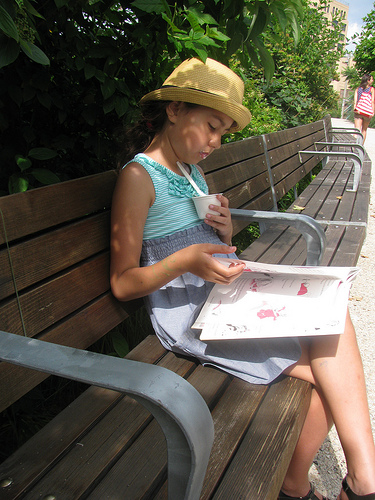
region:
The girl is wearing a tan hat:
[141, 48, 259, 132]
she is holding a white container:
[191, 189, 231, 219]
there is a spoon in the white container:
[174, 160, 206, 201]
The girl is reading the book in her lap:
[195, 258, 356, 344]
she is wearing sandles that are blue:
[339, 478, 373, 499]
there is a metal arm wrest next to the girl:
[217, 204, 333, 265]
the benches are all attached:
[255, 113, 373, 231]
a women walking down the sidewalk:
[355, 75, 373, 151]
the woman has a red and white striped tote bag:
[351, 88, 374, 116]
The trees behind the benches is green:
[222, 18, 333, 134]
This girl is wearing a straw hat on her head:
[182, 47, 271, 130]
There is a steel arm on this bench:
[124, 352, 147, 469]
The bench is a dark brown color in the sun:
[229, 430, 233, 454]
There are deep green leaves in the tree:
[137, 21, 166, 85]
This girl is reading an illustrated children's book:
[269, 274, 297, 305]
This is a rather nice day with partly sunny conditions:
[88, 50, 261, 405]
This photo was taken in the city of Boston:
[103, 35, 272, 339]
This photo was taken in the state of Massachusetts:
[73, 23, 247, 348]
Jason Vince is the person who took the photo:
[80, 60, 223, 461]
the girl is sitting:
[128, 53, 345, 422]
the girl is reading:
[144, 73, 320, 358]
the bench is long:
[27, 143, 361, 404]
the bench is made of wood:
[29, 131, 364, 429]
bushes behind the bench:
[45, 17, 294, 267]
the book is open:
[215, 243, 368, 387]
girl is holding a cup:
[150, 145, 241, 228]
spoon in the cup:
[180, 170, 238, 235]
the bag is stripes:
[353, 84, 373, 120]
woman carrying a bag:
[345, 64, 374, 128]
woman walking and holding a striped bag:
[351, 72, 374, 147]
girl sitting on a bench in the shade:
[109, 49, 374, 498]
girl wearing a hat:
[131, 59, 258, 172]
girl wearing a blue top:
[107, 53, 374, 499]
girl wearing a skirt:
[107, 54, 374, 498]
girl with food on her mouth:
[125, 54, 259, 171]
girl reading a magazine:
[106, 52, 372, 359]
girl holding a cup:
[106, 54, 260, 306]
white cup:
[175, 159, 228, 220]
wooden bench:
[238, 139, 368, 250]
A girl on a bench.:
[107, 55, 373, 498]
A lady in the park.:
[352, 72, 374, 146]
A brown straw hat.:
[138, 55, 251, 133]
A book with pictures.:
[189, 256, 359, 340]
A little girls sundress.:
[120, 152, 301, 384]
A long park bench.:
[2, 112, 371, 495]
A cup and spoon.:
[174, 158, 223, 219]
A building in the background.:
[305, 0, 365, 117]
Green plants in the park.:
[1, 0, 373, 197]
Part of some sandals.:
[277, 476, 373, 498]